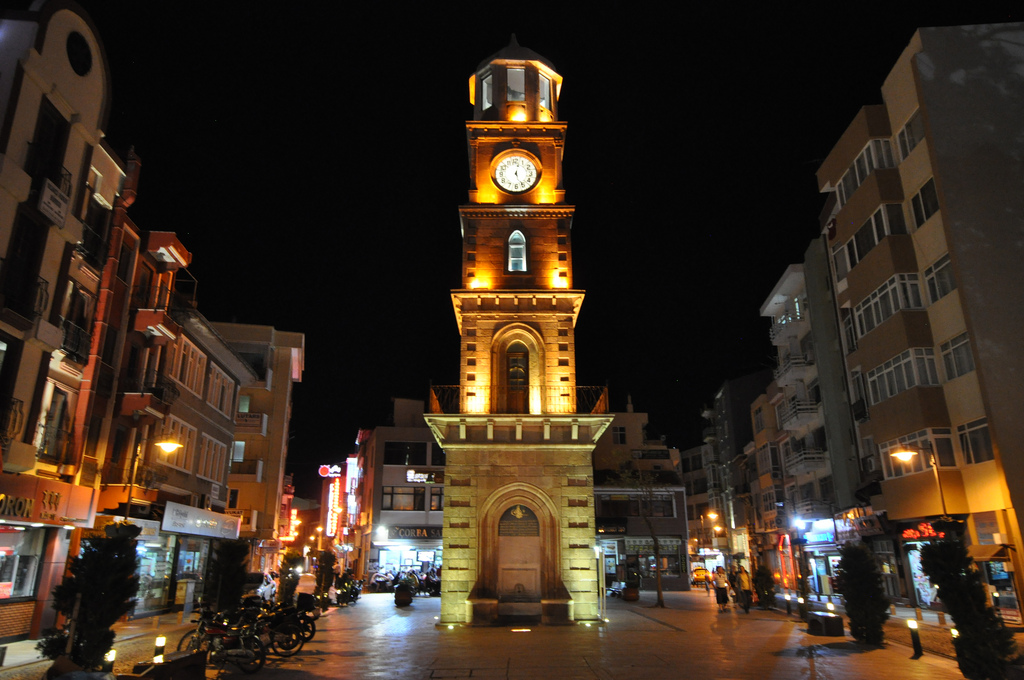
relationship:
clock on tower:
[491, 153, 541, 195] [435, 45, 619, 635]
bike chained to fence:
[185, 610, 265, 669] [184, 595, 321, 678]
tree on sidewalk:
[200, 539, 248, 646] [25, 528, 356, 665]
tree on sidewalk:
[51, 522, 140, 670] [40, 539, 349, 678]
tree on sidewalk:
[311, 535, 340, 603] [112, 444, 357, 680]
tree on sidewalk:
[45, 505, 154, 680] [2, 384, 392, 680]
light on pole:
[890, 419, 916, 502] [888, 382, 951, 635]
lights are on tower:
[419, 110, 595, 675] [445, 203, 582, 355]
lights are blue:
[339, 511, 432, 630] [382, 513, 432, 561]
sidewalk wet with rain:
[248, 581, 858, 680] [439, 624, 584, 680]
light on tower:
[378, 509, 653, 661] [456, 324, 638, 680]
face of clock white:
[475, 138, 564, 206] [469, 203, 610, 243]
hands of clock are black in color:
[505, 161, 534, 188] [439, 205, 610, 322]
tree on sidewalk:
[33, 511, 142, 680] [33, 576, 502, 680]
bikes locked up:
[136, 524, 351, 680] [238, 572, 256, 665]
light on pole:
[885, 440, 922, 477] [919, 427, 948, 514]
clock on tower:
[487, 146, 548, 198] [435, 45, 619, 635]